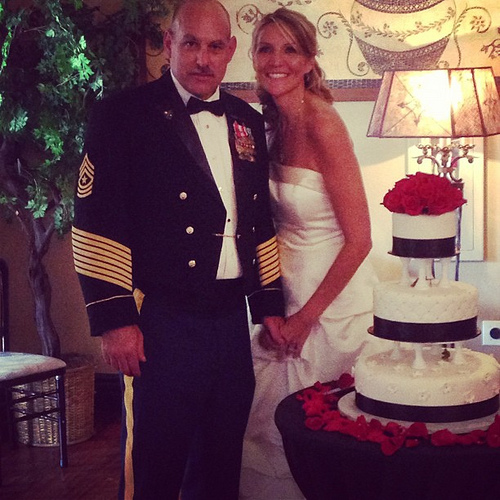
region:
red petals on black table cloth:
[236, 399, 483, 441]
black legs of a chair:
[2, 346, 85, 462]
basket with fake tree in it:
[7, 208, 102, 458]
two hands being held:
[212, 293, 327, 400]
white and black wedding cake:
[342, 281, 482, 461]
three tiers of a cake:
[319, 215, 478, 435]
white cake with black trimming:
[372, 282, 487, 344]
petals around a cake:
[290, 265, 474, 485]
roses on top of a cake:
[366, 164, 471, 270]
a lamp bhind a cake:
[330, 46, 491, 227]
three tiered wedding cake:
[332, 174, 497, 426]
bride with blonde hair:
[235, 15, 381, 487]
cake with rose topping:
[376, 166, 479, 267]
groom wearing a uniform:
[74, 0, 279, 496]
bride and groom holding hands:
[71, 8, 373, 495]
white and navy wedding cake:
[342, 170, 491, 460]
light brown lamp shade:
[361, 46, 498, 147]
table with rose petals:
[266, 403, 494, 497]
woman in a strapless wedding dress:
[258, 23, 399, 475]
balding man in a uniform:
[89, 3, 279, 475]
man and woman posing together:
[57, 13, 426, 489]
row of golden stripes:
[57, 201, 169, 299]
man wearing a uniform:
[42, 43, 319, 490]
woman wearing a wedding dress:
[206, 23, 396, 485]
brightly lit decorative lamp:
[356, 34, 495, 219]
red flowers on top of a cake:
[351, 140, 478, 256]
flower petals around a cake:
[254, 342, 495, 475]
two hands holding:
[234, 288, 344, 408]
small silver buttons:
[164, 177, 229, 314]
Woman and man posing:
[142, 11, 376, 288]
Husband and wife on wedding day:
[63, 17, 445, 479]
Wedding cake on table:
[372, 180, 498, 420]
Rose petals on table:
[290, 380, 455, 480]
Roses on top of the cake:
[384, 156, 471, 231]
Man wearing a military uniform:
[75, 9, 339, 477]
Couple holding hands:
[245, 298, 313, 375]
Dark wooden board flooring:
[44, 461, 111, 490]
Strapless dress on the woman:
[251, 119, 400, 293]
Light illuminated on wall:
[359, 47, 497, 169]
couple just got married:
[65, 3, 380, 476]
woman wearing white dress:
[244, 42, 361, 477]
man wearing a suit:
[59, 4, 297, 485]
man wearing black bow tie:
[60, 7, 275, 482]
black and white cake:
[345, 154, 490, 455]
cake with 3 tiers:
[357, 132, 490, 449]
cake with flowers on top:
[350, 144, 490, 443]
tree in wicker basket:
[5, 7, 93, 445]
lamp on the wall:
[366, 54, 493, 250]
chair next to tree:
[1, 260, 83, 463]